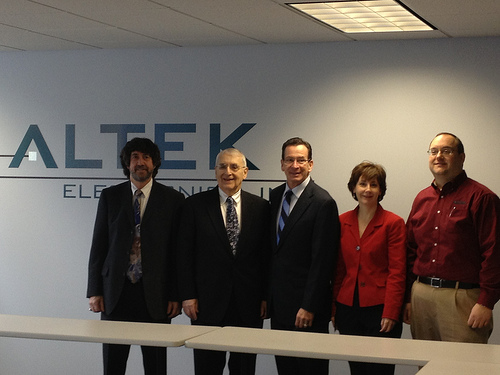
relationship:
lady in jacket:
[332, 161, 407, 375] [338, 210, 407, 322]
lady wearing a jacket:
[332, 161, 407, 375] [330, 203, 412, 309]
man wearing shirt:
[403, 132, 500, 371] [396, 172, 498, 311]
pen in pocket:
[443, 203, 459, 220] [442, 197, 471, 227]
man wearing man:
[403, 132, 500, 371] [260, 136, 340, 373]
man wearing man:
[403, 132, 500, 371] [174, 146, 269, 372]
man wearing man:
[403, 132, 500, 371] [86, 136, 186, 373]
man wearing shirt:
[403, 132, 500, 371] [273, 174, 311, 246]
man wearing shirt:
[403, 132, 500, 371] [215, 188, 243, 229]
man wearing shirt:
[403, 132, 500, 371] [126, 179, 153, 221]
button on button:
[432, 208, 442, 214] [431, 222, 440, 231]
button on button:
[432, 208, 442, 214] [431, 240, 439, 247]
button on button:
[432, 208, 442, 214] [428, 255, 437, 262]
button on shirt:
[432, 208, 442, 214] [396, 172, 498, 311]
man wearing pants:
[403, 132, 500, 371] [407, 272, 492, 341]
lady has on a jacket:
[329, 162, 411, 373] [334, 205, 409, 317]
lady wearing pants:
[332, 161, 407, 375] [327, 296, 396, 373]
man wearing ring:
[266, 136, 342, 375] [302, 322, 309, 327]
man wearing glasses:
[277, 136, 317, 187] [284, 154, 308, 165]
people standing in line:
[81, 129, 498, 374] [94, 127, 485, 338]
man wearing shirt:
[266, 136, 342, 375] [402, 181, 497, 301]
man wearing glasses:
[396, 127, 497, 371] [429, 146, 469, 158]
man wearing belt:
[396, 127, 497, 371] [412, 274, 482, 303]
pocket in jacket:
[292, 217, 309, 238] [260, 167, 330, 351]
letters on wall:
[10, 114, 267, 185] [2, 109, 261, 174]